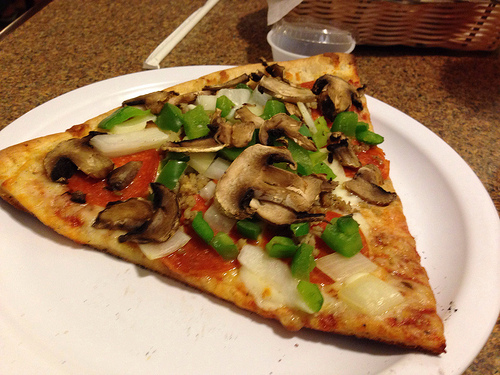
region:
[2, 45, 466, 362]
A piece of pizza with mushrooms and peppers.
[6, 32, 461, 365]
A piece of pizza in a triangle shape.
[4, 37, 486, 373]
A white plate holding a slice of pizza.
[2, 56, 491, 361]
A white plate with a round shape.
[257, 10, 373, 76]
A plastic container with a lid.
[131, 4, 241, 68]
A straw sitting on a brown table.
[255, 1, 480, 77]
A brown basket next to a plastic container.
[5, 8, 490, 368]
A brown table with a slice of pizza.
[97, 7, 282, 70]
A white straw wrapper next to a brown basket.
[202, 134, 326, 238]
A mushroom on top of a slice of pizza.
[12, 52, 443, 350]
the large pizza slice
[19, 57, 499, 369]
the white round plate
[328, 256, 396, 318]
the sliced onion on the pizza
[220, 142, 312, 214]
the fresh cut mushroom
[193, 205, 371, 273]
the cut green bell pepper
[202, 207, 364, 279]
the sliced green bell pepper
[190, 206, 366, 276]
the fresh green bell pepper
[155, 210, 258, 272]
the pepperoni on the pizza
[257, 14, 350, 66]
the small plastic container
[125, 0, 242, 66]
the unopened straw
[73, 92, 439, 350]
a slice of pizza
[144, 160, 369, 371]
a slice of pizza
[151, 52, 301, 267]
a slice of pizza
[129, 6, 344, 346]
a slice of pizza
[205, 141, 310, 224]
cooked mushroom on a pizza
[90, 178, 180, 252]
cooked mushroom on a pizza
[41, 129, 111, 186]
cooked mushroom on a pizza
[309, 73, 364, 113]
cooked mushroom on a pizza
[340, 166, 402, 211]
cooked mushroom on a pizza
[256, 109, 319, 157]
cooked mushroom on a pizza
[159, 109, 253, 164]
cooked mushroom on a pizza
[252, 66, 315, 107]
cooked mushroom on a pizza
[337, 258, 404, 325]
cooked onion on a pizza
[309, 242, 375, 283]
cooked onion on a pizza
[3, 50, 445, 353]
slice of pepperoni pizza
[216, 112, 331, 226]
mushrooms on pizza slice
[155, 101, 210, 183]
diced green peppers on pizza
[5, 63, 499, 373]
white plate holding pizza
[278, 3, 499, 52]
bread basket with liner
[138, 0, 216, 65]
straw in white paper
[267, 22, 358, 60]
small round plastic container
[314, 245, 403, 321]
onions on pepperoni pizza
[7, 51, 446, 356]
pizza slice with onions, peppers, mushrooms, and pepperoni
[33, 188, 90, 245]
melted cheese on pizza